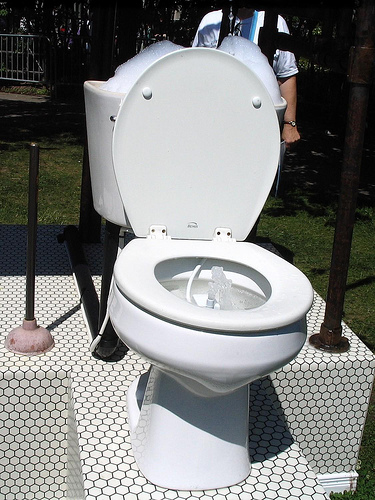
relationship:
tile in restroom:
[22, 398, 38, 415] [0, 41, 372, 498]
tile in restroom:
[0, 280, 374, 500] [0, 41, 372, 498]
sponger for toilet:
[2, 316, 56, 357] [78, 45, 315, 492]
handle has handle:
[16, 139, 40, 323] [21, 139, 40, 323]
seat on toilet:
[114, 223, 315, 335] [78, 45, 315, 492]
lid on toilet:
[105, 42, 281, 245] [78, 45, 315, 492]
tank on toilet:
[78, 71, 289, 232] [78, 45, 315, 492]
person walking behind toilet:
[189, 4, 299, 144] [78, 45, 315, 492]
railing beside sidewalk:
[0, 30, 51, 84] [0, 79, 63, 104]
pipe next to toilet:
[311, 3, 375, 353] [78, 45, 315, 492]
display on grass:
[5, 25, 373, 498] [7, 102, 373, 496]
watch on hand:
[281, 115, 301, 127] [279, 120, 299, 144]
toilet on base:
[78, 45, 315, 492] [119, 344, 260, 491]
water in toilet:
[197, 259, 252, 321] [78, 45, 315, 492]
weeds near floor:
[326, 473, 369, 498] [3, 275, 371, 495]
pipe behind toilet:
[62, 222, 126, 363] [78, 45, 315, 492]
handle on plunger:
[16, 139, 40, 323] [3, 314, 56, 355]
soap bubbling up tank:
[91, 34, 283, 107] [78, 71, 289, 246]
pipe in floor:
[311, 3, 373, 353] [285, 363, 366, 488]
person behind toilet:
[189, 4, 299, 144] [78, 45, 315, 492]